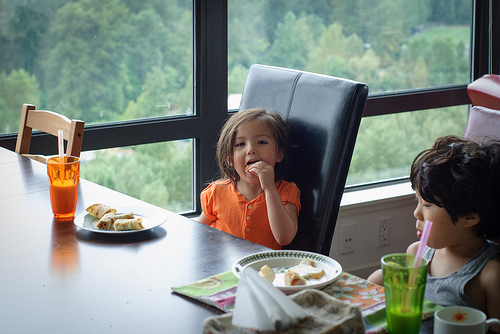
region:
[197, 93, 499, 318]
Two young children sitting at a table.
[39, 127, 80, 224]
An orange class with a straw.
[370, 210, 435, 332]
A green class with a straw.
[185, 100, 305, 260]
A young child wearing on orange shirt.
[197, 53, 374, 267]
A young child sitting in a leather chair.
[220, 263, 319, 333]
A white cloth napkin.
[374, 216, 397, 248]
A white electric outlet.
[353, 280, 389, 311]
A white flower on place mat.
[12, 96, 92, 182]
The top of a wooden chair.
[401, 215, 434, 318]
A pink and white straw in a glass.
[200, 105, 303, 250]
a young girl sitting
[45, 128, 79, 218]
liquid in orange cup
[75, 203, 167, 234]
food on a plate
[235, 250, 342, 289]
food on a plate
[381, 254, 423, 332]
liquid in a green cup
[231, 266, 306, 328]
a tissue sticking out of a box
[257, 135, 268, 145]
eye of a girl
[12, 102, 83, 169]
top of a wooden chair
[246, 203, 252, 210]
button on a girl's shirt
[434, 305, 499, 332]
a small white mug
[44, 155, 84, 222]
a tall orange glass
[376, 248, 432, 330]
a tall green glass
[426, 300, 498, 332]
part of a white coffee mug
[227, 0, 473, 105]
part of a window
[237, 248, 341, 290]
a white plate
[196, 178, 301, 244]
a girl's orange shirt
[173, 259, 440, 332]
a colorful place mat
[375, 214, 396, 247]
a white wall outlet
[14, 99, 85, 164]
part of a brown wooden chair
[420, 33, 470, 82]
part of a tall green tree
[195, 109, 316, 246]
a little girl eating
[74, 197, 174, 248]
a white round plate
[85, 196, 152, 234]
four pieces of food on a plate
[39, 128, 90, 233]
an orange glass with straw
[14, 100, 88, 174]
brown wooden back to chair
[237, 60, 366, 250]
back of a black leather chair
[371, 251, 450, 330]
a green cup with straw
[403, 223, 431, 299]
pink straw in green cup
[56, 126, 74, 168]
white straw in orange cup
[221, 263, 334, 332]
a white napkin ready to use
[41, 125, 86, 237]
an orange glass with milk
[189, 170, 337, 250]
orange shirt on little girl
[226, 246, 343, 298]
a white dish with green trim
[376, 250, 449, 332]
a green cup with milk in it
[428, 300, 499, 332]
a white coffee cup with orange sun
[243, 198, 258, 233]
three white buttons on a shirt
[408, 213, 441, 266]
a pink straw in green cup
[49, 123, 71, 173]
a white straw in orange cup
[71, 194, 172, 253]
a round white plate